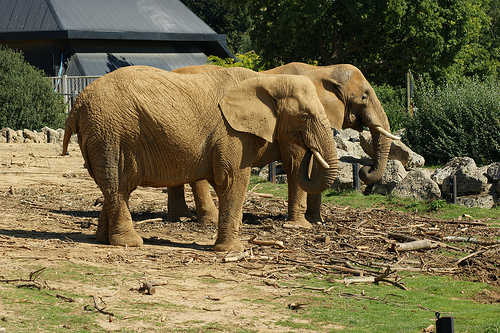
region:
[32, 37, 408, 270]
there are two elephants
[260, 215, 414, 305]
there are branches on the ground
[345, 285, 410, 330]
the grass is green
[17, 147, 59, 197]
the ground is brown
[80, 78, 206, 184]
elephant's skin is wrinkled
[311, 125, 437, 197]
elephants have tusk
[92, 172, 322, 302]
the elephant has four legs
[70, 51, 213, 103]
the roof is gray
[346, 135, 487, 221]
the rocks are rough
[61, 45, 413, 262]
two large elephants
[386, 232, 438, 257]
a piece of wood on the ground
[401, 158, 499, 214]
a large pile of rocks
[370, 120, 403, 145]
ivory tusks of an elephant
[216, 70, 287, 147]
ear of an elephant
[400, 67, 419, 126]
wooden post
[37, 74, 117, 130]
wooden fence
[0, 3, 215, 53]
slanted roof of a building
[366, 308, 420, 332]
green grass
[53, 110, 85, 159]
the tail of an elephant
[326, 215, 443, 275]
some dry sticks on the ground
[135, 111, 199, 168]
stomach of an elephant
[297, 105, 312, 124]
right eye of an elephant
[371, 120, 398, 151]
tusk of an elephant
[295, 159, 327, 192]
trunk of an elephant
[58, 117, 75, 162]
tail of an elephant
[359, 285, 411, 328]
part of some green grass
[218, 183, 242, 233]
right leg of an elephant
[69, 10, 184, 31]
roof of an elephant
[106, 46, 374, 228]
Two elephants are seen.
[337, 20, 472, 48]
trees are green color.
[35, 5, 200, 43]
Roof is grey color.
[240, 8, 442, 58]
Trees are behind the elephant.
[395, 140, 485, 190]
Rock is grey color.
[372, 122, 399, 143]
Tusk is white color.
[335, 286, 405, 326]
Grass is green color.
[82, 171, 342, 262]
Two elephants are standing.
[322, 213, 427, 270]
logs are brown color.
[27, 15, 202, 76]
building is behind the elephant.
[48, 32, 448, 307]
Two large elephants together.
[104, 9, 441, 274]
Some huge elephants amongst some rocks.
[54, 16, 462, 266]
Two big brown elephants outside on a clear day.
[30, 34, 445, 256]
huge elephants together on a bright sunny day.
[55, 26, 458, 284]
Big brown elephants together on a bright sunny day.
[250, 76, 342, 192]
the head of an elephant.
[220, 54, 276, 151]
right ear of an elephant.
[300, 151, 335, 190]
large ivory elephant tusks.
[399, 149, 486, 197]
a set of large rocks.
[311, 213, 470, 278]
broken wood upon the ground.